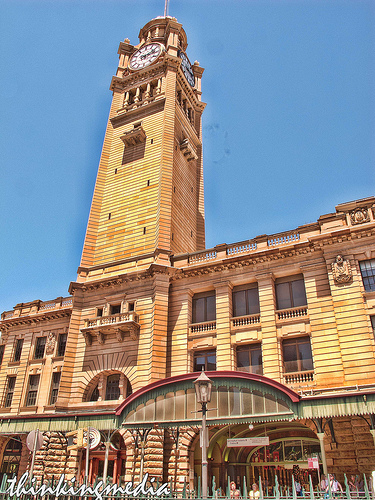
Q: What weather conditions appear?
A: It is clear.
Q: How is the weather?
A: It is clear.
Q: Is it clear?
A: Yes, it is clear.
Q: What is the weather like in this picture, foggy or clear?
A: It is clear.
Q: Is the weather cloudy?
A: No, it is clear.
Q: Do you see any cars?
A: No, there are no cars.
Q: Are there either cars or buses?
A: No, there are no cars or buses.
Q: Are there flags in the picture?
A: No, there are no flags.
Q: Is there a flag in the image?
A: No, there are no flags.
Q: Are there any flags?
A: No, there are no flags.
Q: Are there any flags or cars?
A: No, there are no flags or cars.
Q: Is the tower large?
A: Yes, the tower is large.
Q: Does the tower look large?
A: Yes, the tower is large.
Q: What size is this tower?
A: The tower is large.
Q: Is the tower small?
A: No, the tower is large.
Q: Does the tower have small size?
A: No, the tower is large.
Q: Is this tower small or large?
A: The tower is large.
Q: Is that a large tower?
A: Yes, that is a large tower.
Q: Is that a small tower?
A: No, that is a large tower.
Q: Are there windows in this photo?
A: Yes, there are windows.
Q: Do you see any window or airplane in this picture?
A: Yes, there are windows.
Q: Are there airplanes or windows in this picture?
A: Yes, there are windows.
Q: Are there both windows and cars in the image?
A: No, there are windows but no cars.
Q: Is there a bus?
A: No, there are no buses.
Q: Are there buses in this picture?
A: No, there are no buses.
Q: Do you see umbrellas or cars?
A: No, there are no cars or umbrellas.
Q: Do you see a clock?
A: Yes, there is a clock.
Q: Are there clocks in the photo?
A: Yes, there is a clock.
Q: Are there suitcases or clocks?
A: Yes, there is a clock.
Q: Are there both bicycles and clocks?
A: No, there is a clock but no bikes.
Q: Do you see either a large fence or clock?
A: Yes, there is a large clock.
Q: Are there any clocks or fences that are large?
A: Yes, the clock is large.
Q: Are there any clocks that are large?
A: Yes, there is a large clock.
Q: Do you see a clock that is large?
A: Yes, there is a clock that is large.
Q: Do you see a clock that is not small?
A: Yes, there is a large clock.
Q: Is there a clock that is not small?
A: Yes, there is a large clock.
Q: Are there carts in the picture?
A: No, there are no carts.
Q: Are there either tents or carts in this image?
A: No, there are no carts or tents.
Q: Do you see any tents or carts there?
A: No, there are no carts or tents.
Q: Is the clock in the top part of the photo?
A: Yes, the clock is in the top of the image.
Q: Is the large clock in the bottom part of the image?
A: No, the clock is in the top of the image.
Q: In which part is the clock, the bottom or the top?
A: The clock is in the top of the image.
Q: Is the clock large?
A: Yes, the clock is large.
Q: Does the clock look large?
A: Yes, the clock is large.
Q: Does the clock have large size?
A: Yes, the clock is large.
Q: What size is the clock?
A: The clock is large.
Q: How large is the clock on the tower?
A: The clock is large.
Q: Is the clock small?
A: No, the clock is large.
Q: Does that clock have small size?
A: No, the clock is large.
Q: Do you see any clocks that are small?
A: No, there is a clock but it is large.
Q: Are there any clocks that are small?
A: No, there is a clock but it is large.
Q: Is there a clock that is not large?
A: No, there is a clock but it is large.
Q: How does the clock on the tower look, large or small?
A: The clock is large.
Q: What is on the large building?
A: The clock is on the tower.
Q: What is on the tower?
A: The clock is on the tower.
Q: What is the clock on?
A: The clock is on the tower.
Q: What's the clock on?
A: The clock is on the tower.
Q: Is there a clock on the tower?
A: Yes, there is a clock on the tower.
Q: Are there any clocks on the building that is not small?
A: Yes, there is a clock on the tower.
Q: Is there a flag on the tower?
A: No, there is a clock on the tower.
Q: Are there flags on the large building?
A: No, there is a clock on the tower.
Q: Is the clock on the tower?
A: Yes, the clock is on the tower.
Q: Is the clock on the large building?
A: Yes, the clock is on the tower.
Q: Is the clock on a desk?
A: No, the clock is on the tower.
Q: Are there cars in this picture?
A: No, there are no cars.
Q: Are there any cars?
A: No, there are no cars.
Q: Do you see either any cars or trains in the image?
A: No, there are no cars or trains.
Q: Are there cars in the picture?
A: No, there are no cars.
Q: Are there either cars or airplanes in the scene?
A: No, there are no cars or airplanes.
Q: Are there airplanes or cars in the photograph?
A: No, there are no cars or airplanes.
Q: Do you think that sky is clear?
A: Yes, the sky is clear.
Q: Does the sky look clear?
A: Yes, the sky is clear.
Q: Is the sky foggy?
A: No, the sky is clear.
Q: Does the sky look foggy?
A: No, the sky is clear.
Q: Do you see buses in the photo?
A: No, there are no buses.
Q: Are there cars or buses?
A: No, there are no buses or cars.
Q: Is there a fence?
A: Yes, there is a fence.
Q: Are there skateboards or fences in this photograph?
A: Yes, there is a fence.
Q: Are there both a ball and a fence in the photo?
A: No, there is a fence but no balls.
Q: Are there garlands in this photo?
A: No, there are no garlands.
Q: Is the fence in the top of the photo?
A: No, the fence is in the bottom of the image.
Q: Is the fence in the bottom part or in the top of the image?
A: The fence is in the bottom of the image.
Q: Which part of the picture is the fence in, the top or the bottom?
A: The fence is in the bottom of the image.